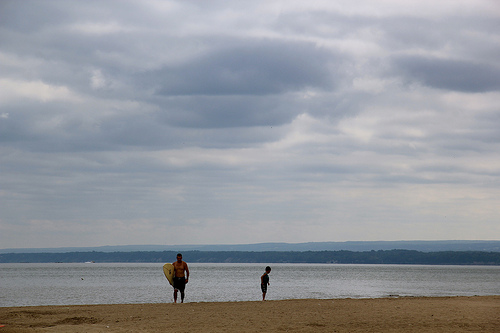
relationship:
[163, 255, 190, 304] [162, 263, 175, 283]
man with surfboard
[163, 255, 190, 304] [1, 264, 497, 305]
man walking out of an ocean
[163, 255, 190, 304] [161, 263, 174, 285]
man holding surfboard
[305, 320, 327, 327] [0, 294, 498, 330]
track on sand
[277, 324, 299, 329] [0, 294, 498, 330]
track on sand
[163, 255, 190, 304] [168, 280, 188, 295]
man wearing shorts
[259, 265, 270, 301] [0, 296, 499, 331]
boy on beach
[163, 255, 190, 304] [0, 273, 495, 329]
man on beach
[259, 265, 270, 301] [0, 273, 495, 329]
boy on beach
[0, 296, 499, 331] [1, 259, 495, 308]
beach in front of water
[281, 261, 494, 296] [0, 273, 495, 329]
water after beach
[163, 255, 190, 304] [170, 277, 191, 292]
man wearing swim trunks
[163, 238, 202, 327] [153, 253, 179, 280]
man carrying a surfboard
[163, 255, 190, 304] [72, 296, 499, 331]
man standing on a beach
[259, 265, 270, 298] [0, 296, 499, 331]
boy standing on a beach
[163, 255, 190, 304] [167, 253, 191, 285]
man has tank top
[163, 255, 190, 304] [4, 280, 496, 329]
man on a beach